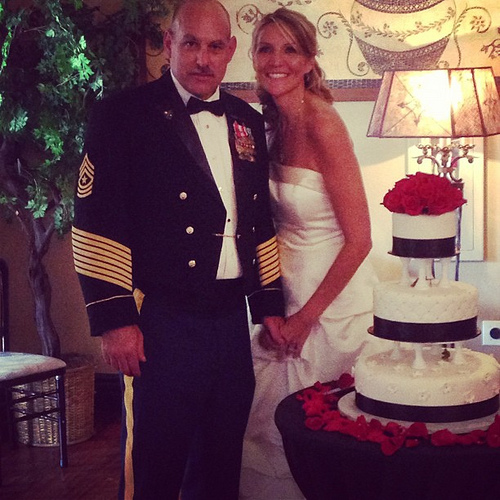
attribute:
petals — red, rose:
[302, 382, 356, 435]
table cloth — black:
[277, 388, 498, 498]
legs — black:
[0, 369, 66, 476]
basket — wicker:
[13, 360, 101, 449]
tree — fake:
[3, 1, 108, 354]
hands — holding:
[256, 309, 313, 362]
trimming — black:
[354, 394, 499, 425]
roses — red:
[369, 172, 474, 216]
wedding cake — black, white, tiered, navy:
[339, 213, 497, 432]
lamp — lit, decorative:
[366, 64, 499, 175]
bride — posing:
[243, 7, 391, 489]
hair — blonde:
[276, 10, 336, 95]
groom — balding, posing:
[72, 5, 284, 493]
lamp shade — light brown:
[369, 68, 500, 136]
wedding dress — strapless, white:
[248, 155, 386, 499]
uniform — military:
[64, 74, 294, 499]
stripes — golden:
[68, 229, 134, 289]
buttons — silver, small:
[176, 190, 199, 269]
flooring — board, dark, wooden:
[0, 432, 127, 497]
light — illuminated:
[421, 86, 462, 115]